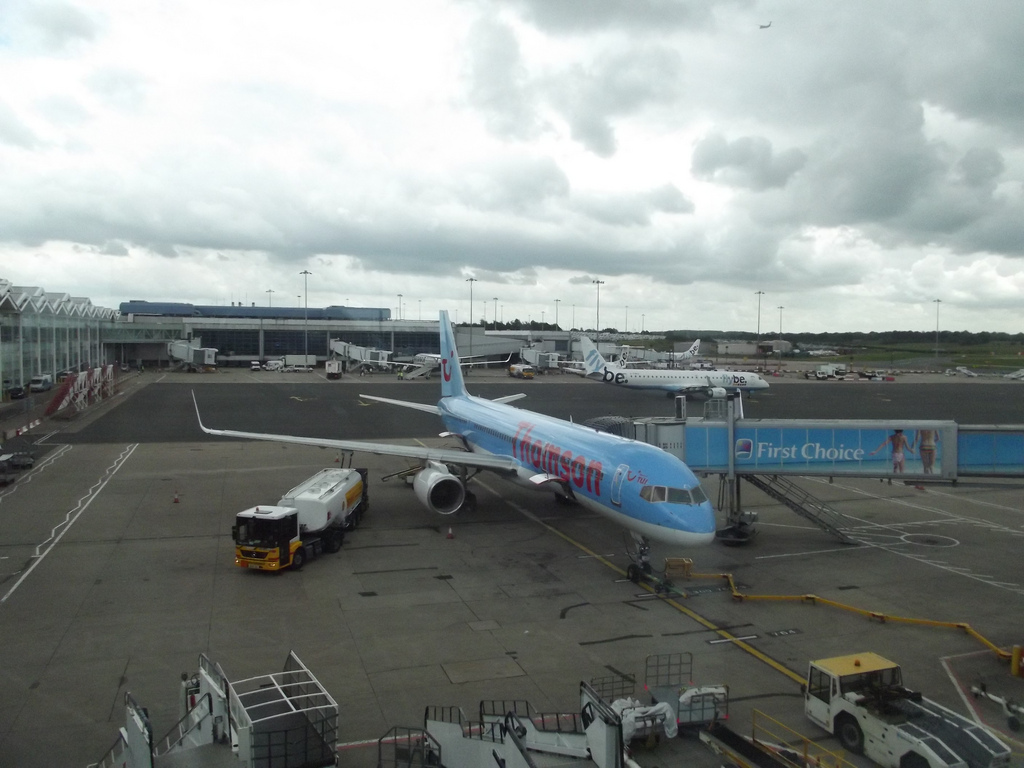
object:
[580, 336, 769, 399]
airport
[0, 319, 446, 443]
airport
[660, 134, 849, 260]
clouds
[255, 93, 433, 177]
clouds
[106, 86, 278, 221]
clouds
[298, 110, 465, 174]
sky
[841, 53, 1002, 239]
sky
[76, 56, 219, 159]
sky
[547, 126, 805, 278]
sky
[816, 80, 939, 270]
sky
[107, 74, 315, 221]
sky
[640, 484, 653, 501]
window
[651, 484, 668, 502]
window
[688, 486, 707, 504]
window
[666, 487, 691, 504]
window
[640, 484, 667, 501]
window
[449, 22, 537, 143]
cloud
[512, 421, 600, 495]
lettering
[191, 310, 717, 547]
airplane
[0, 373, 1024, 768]
ground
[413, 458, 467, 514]
engine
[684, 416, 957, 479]
billboard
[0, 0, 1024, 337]
clouds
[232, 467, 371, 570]
truck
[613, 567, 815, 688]
line